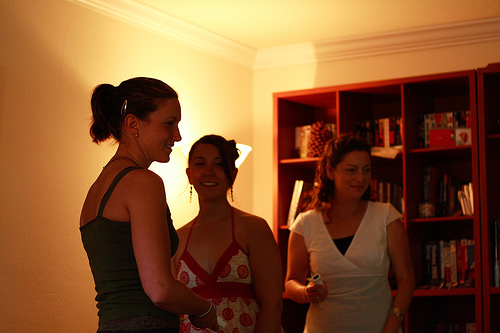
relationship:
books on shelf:
[280, 89, 481, 155] [262, 69, 484, 316]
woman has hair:
[260, 111, 389, 325] [211, 120, 238, 161]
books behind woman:
[280, 89, 481, 155] [260, 111, 389, 325]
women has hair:
[73, 41, 444, 329] [211, 120, 238, 161]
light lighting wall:
[223, 123, 251, 181] [200, 7, 271, 122]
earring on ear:
[217, 187, 239, 209] [228, 157, 245, 183]